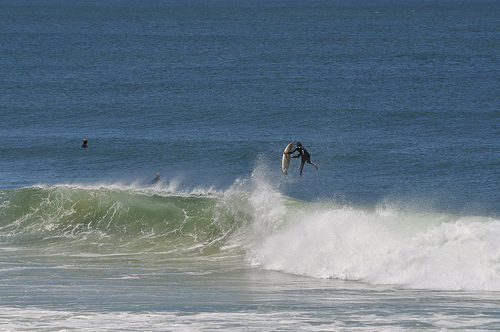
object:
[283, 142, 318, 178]
person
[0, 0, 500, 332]
ocean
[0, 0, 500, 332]
sky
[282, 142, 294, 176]
surfboard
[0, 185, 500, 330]
foam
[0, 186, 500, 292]
wave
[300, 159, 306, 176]
legs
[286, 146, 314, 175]
wetsuit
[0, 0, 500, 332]
water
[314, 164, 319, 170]
foot